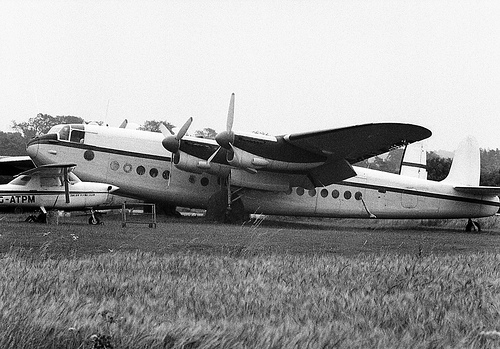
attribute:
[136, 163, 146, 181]
circle — small, round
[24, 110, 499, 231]
plane — large, white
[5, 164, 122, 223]
plane — small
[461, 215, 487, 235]
wheel — down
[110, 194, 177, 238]
cart — metal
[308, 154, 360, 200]
wingflap — down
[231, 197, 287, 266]
grass — tall